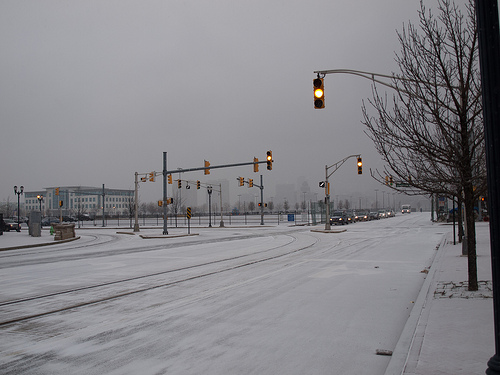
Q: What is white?
A: Snow.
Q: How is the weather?
A: Cold.